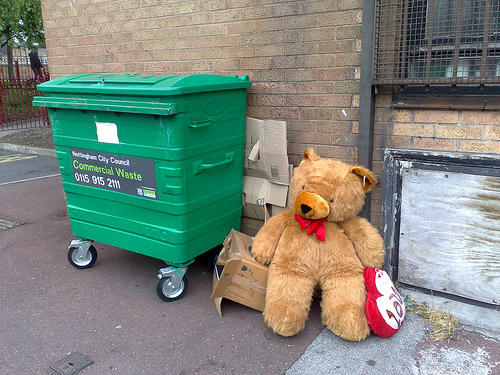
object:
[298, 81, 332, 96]
bricks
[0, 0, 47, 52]
tree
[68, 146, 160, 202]
sticker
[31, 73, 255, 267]
bin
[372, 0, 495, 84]
fence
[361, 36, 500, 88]
bars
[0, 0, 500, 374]
alley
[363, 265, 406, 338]
decoration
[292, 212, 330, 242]
bow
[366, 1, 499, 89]
window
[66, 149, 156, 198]
info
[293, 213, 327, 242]
ribbon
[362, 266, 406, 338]
pillow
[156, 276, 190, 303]
wheel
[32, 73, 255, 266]
garbage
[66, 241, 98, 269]
wheel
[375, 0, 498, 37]
bars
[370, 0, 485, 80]
wire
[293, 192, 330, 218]
nose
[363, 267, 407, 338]
heart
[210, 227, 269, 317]
box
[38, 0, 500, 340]
building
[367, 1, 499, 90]
gate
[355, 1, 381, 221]
pole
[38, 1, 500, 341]
wall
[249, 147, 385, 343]
bear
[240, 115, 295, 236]
box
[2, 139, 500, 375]
ground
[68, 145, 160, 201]
sign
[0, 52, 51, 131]
fence